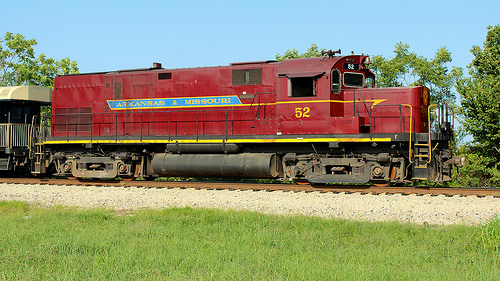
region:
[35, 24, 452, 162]
The train is red.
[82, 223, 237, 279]
The grass is green.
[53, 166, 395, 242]
Dirt is next to the track.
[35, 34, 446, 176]
The train is on the track.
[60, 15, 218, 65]
The sky is blue.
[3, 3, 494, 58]
The sky is clear.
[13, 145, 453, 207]
The track is brown.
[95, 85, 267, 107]
The text is yellow.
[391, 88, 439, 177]
The railing is yellow.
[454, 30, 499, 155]
The trees are green.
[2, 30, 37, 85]
a green tree in a distance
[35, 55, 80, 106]
a green tree in a distance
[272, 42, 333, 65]
a green tree in a distance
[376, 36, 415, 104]
a green tree in a distance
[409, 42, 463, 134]
a green tree in a distance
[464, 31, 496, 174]
a green tree in a distance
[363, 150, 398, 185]
the wheel of a train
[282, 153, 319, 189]
the wheel of a train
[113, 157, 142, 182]
the wheel of a train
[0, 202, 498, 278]
green healthy grass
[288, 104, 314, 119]
yellow painted number on train.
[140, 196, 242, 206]
pebbles next to track.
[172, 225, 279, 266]
grass near the track.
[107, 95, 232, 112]
words on side of train.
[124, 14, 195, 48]
clear blue sky above.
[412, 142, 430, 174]
step ladder up to train.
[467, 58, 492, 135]
green leaves on trees.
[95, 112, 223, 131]
railing alongside the train.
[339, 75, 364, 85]
windshield on train car.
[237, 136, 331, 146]
yellow stripe on train car.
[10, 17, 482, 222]
Train with red paint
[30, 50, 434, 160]
Red pain on a train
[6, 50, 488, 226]
Train on train tracks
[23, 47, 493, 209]
Red train on train tracks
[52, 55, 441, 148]
Train with the number 52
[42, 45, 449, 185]
Red train with number 52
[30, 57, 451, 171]
The number 52 on a train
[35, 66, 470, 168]
The number 52 on a red train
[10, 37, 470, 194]
Red train with yellow stripe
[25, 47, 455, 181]
Red train with blue on it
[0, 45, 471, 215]
beautiful red train engine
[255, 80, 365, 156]
a train with the number 5 on it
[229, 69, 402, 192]
a red trail with a 2 on it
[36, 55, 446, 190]
a big reg train engine with the letter m on it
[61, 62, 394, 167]
a big reg train engine with the letter i on it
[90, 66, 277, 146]
a big reg train engine with the letter s on it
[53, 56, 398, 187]
a big reg train engine with the letter o on it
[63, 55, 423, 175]
a big reg train engine with the letter u on it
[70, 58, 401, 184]
a big reg train engine with the letter r on it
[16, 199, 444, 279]
green grass beside the train track